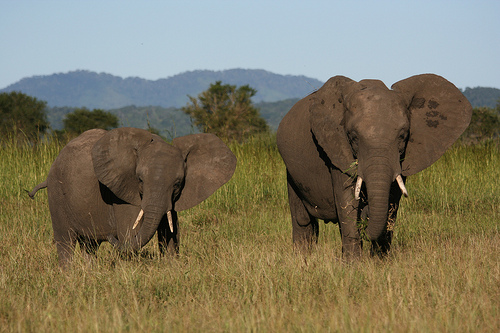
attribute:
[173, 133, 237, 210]
ear — wide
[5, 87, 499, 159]
trees — tall, green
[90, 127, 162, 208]
ear — wide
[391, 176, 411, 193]
tusks — white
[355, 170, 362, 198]
tusks — white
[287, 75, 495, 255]
elephant — large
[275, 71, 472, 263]
elephant — large, brown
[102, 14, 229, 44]
sky — clear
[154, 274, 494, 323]
grasslands — brown, green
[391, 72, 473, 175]
ear — wide, dark brown, light brown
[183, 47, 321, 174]
tree — green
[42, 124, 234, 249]
elephant — brown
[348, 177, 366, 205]
tusk — white, curved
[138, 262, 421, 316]
grass — high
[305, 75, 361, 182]
ear — wide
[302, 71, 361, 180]
ear — wide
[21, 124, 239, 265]
elephant — brown, smaller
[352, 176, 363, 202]
tusk — white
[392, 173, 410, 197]
tusk — white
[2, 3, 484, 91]
sky — cloudless, blue, clear